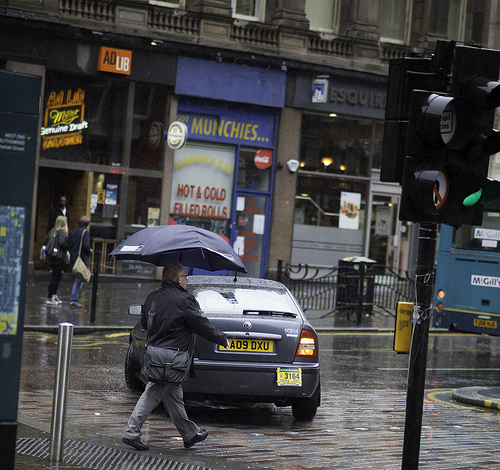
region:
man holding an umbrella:
[107, 220, 247, 450]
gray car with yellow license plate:
[121, 271, 320, 422]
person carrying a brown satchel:
[66, 210, 94, 309]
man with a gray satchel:
[119, 259, 231, 450]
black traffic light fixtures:
[378, 34, 498, 231]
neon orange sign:
[40, 83, 89, 151]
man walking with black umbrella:
[106, 222, 246, 448]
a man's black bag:
[143, 301, 196, 383]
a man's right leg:
[122, 380, 169, 452]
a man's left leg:
[167, 381, 208, 446]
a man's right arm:
[185, 295, 230, 350]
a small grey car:
[127, 275, 319, 420]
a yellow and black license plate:
[222, 337, 274, 354]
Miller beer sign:
[42, 89, 89, 155]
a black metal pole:
[401, 221, 441, 468]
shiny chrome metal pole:
[46, 321, 73, 463]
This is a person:
[124, 238, 211, 469]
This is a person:
[70, 206, 109, 308]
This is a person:
[41, 213, 75, 303]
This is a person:
[44, 188, 71, 220]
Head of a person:
[155, 253, 192, 290]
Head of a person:
[77, 208, 94, 233]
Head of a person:
[53, 212, 72, 235]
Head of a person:
[55, 193, 74, 208]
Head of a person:
[157, 253, 207, 299]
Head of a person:
[52, 210, 70, 229]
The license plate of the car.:
[214, 333, 275, 350]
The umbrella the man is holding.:
[114, 218, 244, 270]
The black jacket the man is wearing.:
[141, 280, 218, 351]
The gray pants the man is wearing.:
[130, 381, 199, 436]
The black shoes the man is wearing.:
[111, 428, 206, 453]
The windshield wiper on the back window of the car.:
[244, 302, 296, 321]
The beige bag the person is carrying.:
[73, 224, 93, 280]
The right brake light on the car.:
[295, 326, 317, 361]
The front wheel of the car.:
[121, 338, 143, 388]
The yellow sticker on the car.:
[274, 364, 305, 386]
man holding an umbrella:
[108, 216, 234, 447]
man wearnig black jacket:
[108, 208, 228, 456]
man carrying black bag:
[112, 222, 222, 459]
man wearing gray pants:
[120, 222, 206, 467]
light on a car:
[295, 315, 325, 366]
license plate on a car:
[276, 360, 311, 395]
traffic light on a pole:
[390, 40, 497, 237]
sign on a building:
[300, 71, 331, 116]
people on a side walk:
[41, 207, 87, 306]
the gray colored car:
[123, 272, 321, 422]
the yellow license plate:
[218, 336, 274, 351]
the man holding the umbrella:
[107, 223, 248, 448]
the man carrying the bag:
[122, 260, 229, 449]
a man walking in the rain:
[129, 259, 225, 445]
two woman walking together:
[35, 203, 94, 345]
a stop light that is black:
[372, 52, 495, 331]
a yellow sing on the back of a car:
[228, 359, 343, 410]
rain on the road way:
[328, 349, 385, 419]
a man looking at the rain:
[50, 168, 92, 234]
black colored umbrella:
[113, 211, 258, 281]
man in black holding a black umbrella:
[105, 255, 212, 447]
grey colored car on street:
[131, 267, 322, 417]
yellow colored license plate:
[210, 330, 280, 360]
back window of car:
[166, 276, 287, 316]